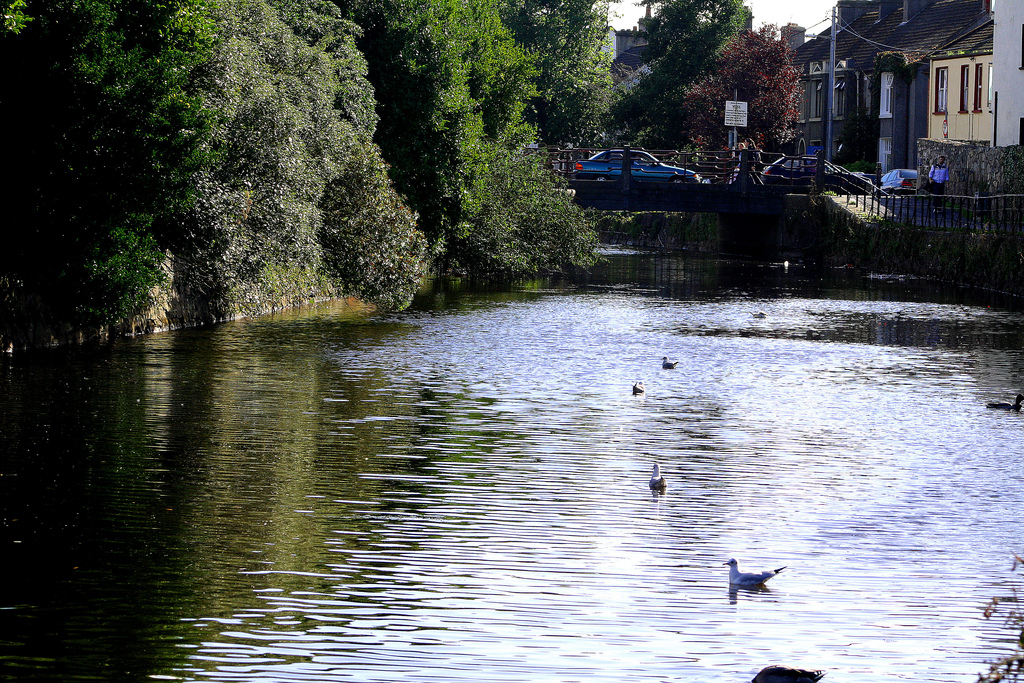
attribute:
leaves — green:
[385, 97, 660, 295]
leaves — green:
[353, 138, 630, 357]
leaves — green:
[382, 27, 610, 190]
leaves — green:
[268, 85, 487, 202]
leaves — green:
[96, 147, 309, 217]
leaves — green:
[90, 59, 332, 196]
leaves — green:
[81, 68, 244, 202]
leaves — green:
[166, 47, 356, 228]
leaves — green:
[151, 83, 428, 246]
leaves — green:
[122, 100, 318, 263]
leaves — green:
[385, 39, 601, 220]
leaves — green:
[455, 205, 621, 289]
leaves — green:
[374, 27, 537, 144]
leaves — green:
[388, 144, 595, 290]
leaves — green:
[315, 45, 551, 249]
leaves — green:
[221, 208, 487, 351]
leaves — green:
[280, 77, 511, 243]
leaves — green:
[99, 167, 248, 295]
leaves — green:
[93, 45, 362, 299]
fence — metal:
[547, 141, 816, 193]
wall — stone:
[914, 137, 1017, 198]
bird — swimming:
[728, 554, 783, 586]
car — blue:
[570, 143, 695, 179]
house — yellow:
[835, 11, 1014, 148]